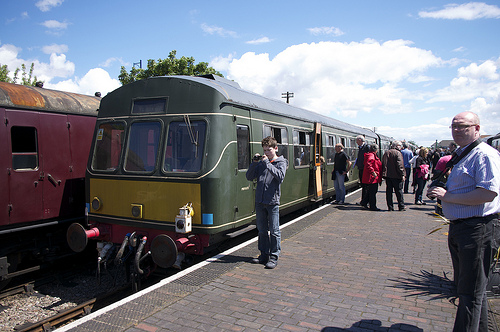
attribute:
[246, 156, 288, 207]
sweater — gray, grey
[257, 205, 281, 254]
boys jeans — gray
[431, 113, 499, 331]
man — bald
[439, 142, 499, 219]
shirt — blue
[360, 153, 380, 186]
sweater — red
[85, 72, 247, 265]
train — yellow, green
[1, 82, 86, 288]
train — red, black, rusty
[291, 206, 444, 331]
station — brick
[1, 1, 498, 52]
sky — blue, cloudy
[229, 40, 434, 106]
clouds — white, fluffy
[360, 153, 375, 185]
jacket — red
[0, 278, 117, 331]
train tracks — steel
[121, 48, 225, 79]
tree — green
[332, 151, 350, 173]
shirt — black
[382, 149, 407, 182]
coat — brown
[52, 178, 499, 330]
platform — brick, red, black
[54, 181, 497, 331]
road — brick